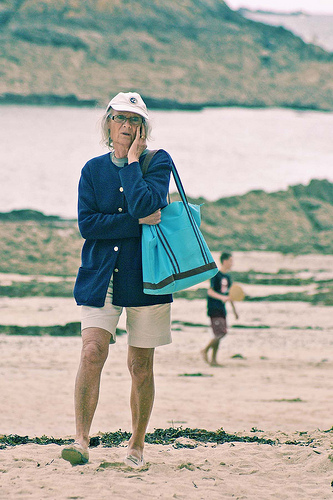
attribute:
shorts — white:
[77, 269, 173, 349]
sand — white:
[2, 439, 329, 497]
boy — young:
[199, 250, 238, 366]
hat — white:
[88, 73, 172, 128]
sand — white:
[63, 456, 173, 488]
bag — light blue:
[140, 148, 218, 294]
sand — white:
[2, 253, 332, 499]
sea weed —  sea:
[0, 425, 306, 453]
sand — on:
[206, 462, 312, 486]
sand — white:
[249, 382, 279, 413]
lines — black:
[133, 193, 222, 288]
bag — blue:
[133, 210, 212, 297]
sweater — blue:
[72, 147, 173, 309]